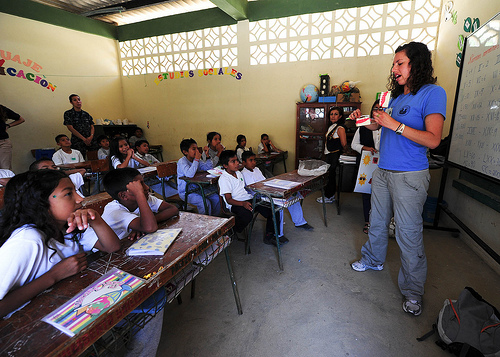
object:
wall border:
[0, 1, 412, 41]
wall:
[0, 4, 125, 170]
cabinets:
[295, 101, 363, 193]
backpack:
[415, 286, 499, 356]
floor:
[159, 184, 499, 356]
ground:
[243, 190, 378, 335]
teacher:
[0, 103, 26, 170]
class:
[0, 130, 328, 355]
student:
[101, 167, 180, 241]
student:
[176, 137, 221, 216]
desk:
[179, 143, 288, 212]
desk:
[245, 160, 330, 270]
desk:
[0, 209, 251, 353]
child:
[217, 150, 283, 248]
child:
[240, 150, 314, 244]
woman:
[316, 105, 347, 203]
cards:
[355, 117, 371, 127]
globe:
[300, 84, 319, 103]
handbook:
[41, 266, 151, 336]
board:
[447, 13, 500, 184]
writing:
[0, 49, 57, 92]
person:
[63, 93, 96, 160]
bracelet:
[91, 134, 94, 136]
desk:
[244, 164, 335, 269]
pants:
[359, 168, 431, 301]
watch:
[396, 123, 406, 135]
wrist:
[396, 118, 408, 133]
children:
[0, 126, 300, 310]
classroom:
[3, 2, 495, 354]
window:
[249, 0, 442, 67]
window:
[119, 23, 241, 75]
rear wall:
[115, 4, 456, 202]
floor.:
[233, 269, 323, 350]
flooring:
[165, 155, 496, 347]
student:
[0, 169, 167, 356]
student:
[201, 131, 225, 162]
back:
[0, 8, 133, 214]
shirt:
[375, 83, 445, 173]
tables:
[0, 205, 250, 355]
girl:
[351, 41, 447, 315]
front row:
[7, 160, 347, 355]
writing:
[452, 47, 497, 172]